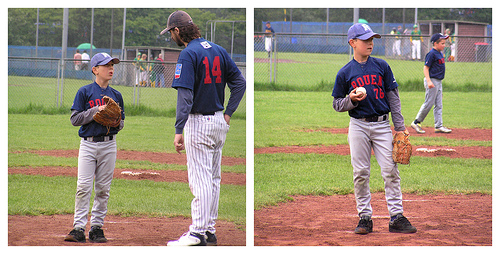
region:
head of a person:
[82, 38, 123, 96]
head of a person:
[162, 15, 210, 50]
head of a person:
[337, 15, 378, 66]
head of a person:
[423, 23, 458, 48]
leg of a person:
[433, 72, 463, 137]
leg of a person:
[407, 91, 435, 135]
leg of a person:
[379, 146, 419, 206]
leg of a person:
[339, 139, 379, 200]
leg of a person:
[183, 159, 227, 227]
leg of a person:
[65, 148, 105, 233]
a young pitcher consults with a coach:
[61, 10, 244, 245]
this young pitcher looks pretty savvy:
[322, 15, 429, 239]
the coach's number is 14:
[194, 49, 226, 89]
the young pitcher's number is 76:
[366, 81, 392, 103]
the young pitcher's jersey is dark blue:
[328, 50, 403, 122]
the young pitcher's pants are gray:
[340, 110, 412, 225]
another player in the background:
[408, 28, 457, 138]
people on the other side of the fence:
[71, 37, 169, 87]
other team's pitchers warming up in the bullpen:
[383, 20, 463, 62]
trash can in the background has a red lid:
[469, 35, 493, 65]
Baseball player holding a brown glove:
[66, 52, 126, 239]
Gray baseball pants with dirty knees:
[73, 134, 116, 226]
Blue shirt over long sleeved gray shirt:
[171, 41, 246, 133]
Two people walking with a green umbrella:
[72, 41, 99, 68]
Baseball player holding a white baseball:
[328, 20, 413, 229]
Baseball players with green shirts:
[388, 27, 421, 57]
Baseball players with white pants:
[391, 39, 423, 59]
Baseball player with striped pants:
[181, 106, 229, 240]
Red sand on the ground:
[274, 201, 347, 243]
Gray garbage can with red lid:
[473, 41, 488, 61]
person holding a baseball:
[332, 60, 387, 126]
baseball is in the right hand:
[329, 73, 374, 120]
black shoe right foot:
[350, 211, 375, 233]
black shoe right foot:
[64, 219, 84, 250]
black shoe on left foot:
[91, 223, 110, 240]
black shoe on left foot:
[392, 206, 416, 238]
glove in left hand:
[391, 130, 418, 167]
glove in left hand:
[98, 98, 122, 130]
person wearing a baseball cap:
[348, 18, 377, 48]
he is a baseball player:
[319, 15, 457, 251]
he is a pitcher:
[322, 4, 438, 252]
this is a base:
[403, 137, 488, 159]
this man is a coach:
[145, 9, 261, 250]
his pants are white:
[170, 113, 235, 251]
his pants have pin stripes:
[169, 104, 249, 252]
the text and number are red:
[338, 65, 396, 107]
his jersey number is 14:
[199, 32, 229, 94]